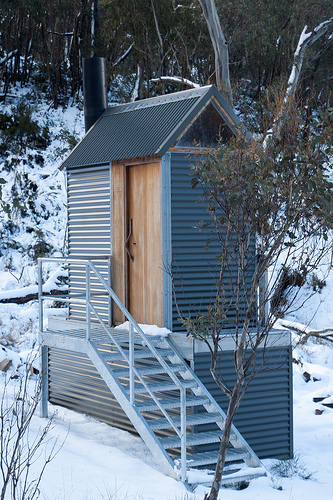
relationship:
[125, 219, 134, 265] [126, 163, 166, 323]
handle on door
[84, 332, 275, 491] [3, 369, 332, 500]
stairs to ground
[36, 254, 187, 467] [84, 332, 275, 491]
rail up stairs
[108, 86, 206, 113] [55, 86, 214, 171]
rivets in roof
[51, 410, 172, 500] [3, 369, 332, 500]
snow on ground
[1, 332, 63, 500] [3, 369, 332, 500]
bushes on ground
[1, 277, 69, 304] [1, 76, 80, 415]
log on hill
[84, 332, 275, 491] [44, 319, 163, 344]
stairs to landing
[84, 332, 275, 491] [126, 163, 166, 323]
stairs to door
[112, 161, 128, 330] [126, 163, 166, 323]
inset next to door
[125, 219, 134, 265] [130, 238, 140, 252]
handle has a lock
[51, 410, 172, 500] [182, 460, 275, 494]
snow on step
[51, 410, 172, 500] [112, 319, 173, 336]
snow on doorstep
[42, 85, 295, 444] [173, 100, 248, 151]
cabin has one window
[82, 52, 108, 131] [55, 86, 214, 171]
chimney by roof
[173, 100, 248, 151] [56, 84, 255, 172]
window on roof